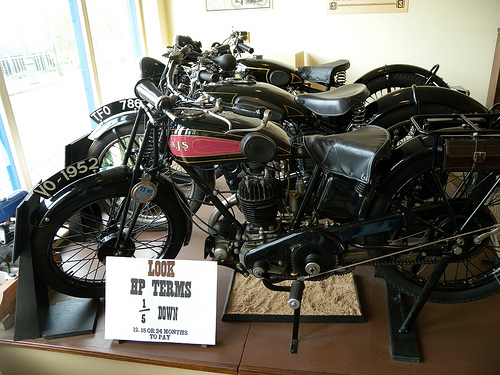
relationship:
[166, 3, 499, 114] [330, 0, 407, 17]
wall has a picture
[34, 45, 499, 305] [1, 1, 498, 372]
bike in a shop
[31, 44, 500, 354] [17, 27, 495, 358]
bike are on display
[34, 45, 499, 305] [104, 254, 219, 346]
bike has an ad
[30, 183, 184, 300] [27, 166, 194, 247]
tire has a cover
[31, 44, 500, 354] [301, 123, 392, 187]
bike have seats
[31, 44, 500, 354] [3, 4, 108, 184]
bike in a window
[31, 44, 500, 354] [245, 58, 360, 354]
bike are in a row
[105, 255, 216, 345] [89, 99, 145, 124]
sign says tfo 786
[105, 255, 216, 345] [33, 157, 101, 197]
sign says vo 1952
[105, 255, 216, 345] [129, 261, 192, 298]
sign says look hp terms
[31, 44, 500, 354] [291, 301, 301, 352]
bike has a kickstand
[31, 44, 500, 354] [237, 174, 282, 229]
bike has an engine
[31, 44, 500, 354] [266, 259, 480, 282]
bike has a chain